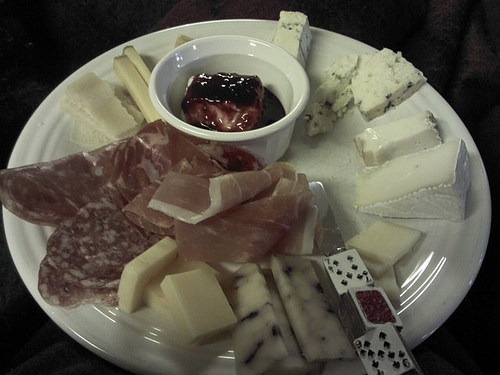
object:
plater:
[57, 12, 463, 350]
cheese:
[351, 49, 426, 122]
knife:
[305, 180, 419, 374]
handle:
[322, 247, 417, 373]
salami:
[42, 196, 159, 310]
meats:
[3, 134, 166, 222]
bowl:
[148, 35, 311, 165]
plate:
[1, 17, 491, 375]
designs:
[320, 247, 415, 373]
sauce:
[194, 71, 257, 100]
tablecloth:
[25, 3, 96, 58]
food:
[7, 10, 468, 372]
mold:
[383, 94, 398, 113]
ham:
[150, 165, 301, 264]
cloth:
[411, 3, 497, 60]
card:
[350, 325, 415, 374]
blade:
[308, 179, 347, 252]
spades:
[350, 264, 359, 271]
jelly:
[266, 89, 289, 124]